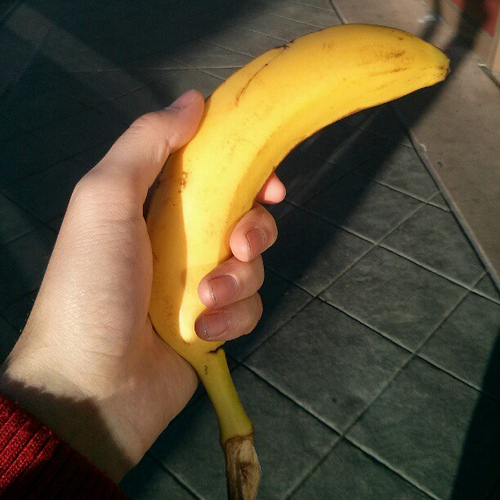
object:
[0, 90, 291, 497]
people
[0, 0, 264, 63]
outdoors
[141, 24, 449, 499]
banana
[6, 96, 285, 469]
hand